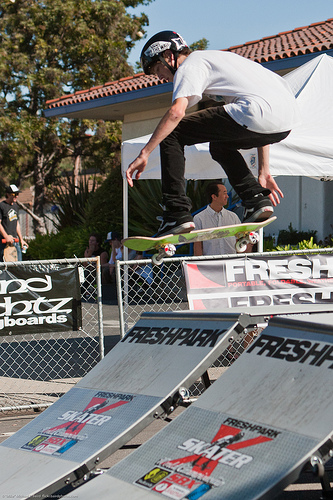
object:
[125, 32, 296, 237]
man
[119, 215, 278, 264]
skateboard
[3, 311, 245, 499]
ramp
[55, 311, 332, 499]
ramp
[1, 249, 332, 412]
fence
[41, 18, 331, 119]
roof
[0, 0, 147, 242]
tree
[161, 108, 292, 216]
pants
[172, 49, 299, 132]
shirt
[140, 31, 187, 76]
helmet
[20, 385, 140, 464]
sticker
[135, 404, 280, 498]
sticker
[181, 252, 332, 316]
sign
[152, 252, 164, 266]
wheel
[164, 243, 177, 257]
wheel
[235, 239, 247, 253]
wheel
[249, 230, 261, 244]
wheel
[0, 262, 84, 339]
sign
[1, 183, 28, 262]
man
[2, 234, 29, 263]
skateboard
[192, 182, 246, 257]
man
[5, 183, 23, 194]
hat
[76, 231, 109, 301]
people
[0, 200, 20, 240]
shirt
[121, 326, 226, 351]
logo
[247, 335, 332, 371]
logo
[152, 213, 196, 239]
shoe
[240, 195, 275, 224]
shoe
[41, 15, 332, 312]
building